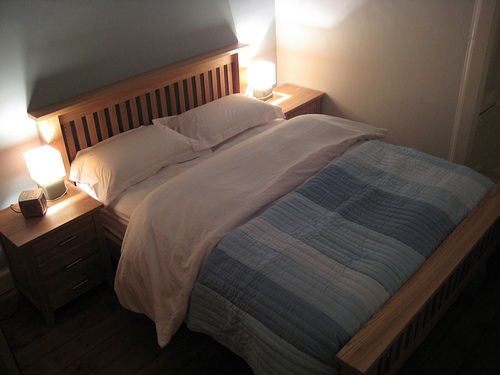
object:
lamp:
[23, 145, 69, 203]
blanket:
[187, 141, 497, 375]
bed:
[24, 43, 500, 375]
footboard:
[369, 216, 500, 374]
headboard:
[27, 42, 255, 167]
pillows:
[152, 92, 283, 153]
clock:
[15, 189, 46, 215]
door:
[464, 15, 500, 174]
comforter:
[70, 93, 499, 374]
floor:
[34, 316, 200, 374]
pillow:
[67, 122, 212, 210]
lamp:
[247, 58, 280, 101]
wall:
[0, 0, 483, 212]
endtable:
[0, 180, 118, 324]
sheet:
[113, 113, 288, 218]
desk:
[268, 84, 326, 120]